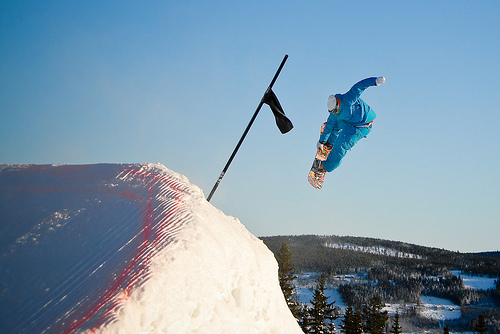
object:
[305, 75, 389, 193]
skier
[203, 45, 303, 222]
pole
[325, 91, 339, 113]
hat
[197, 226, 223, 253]
snow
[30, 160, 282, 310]
cap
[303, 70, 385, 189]
man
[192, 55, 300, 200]
skiis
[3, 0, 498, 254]
blue sky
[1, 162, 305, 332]
snow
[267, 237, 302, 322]
tree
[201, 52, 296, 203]
flag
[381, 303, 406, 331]
trees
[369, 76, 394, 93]
glove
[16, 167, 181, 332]
paint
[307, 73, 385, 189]
snowboarder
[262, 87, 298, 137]
flag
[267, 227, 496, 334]
mountainside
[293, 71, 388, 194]
trick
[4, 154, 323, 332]
field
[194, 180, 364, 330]
cliff